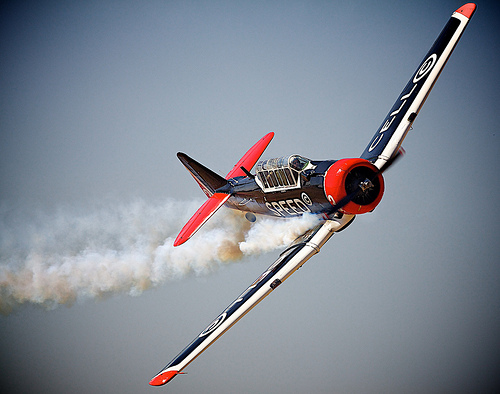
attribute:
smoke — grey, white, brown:
[2, 194, 312, 313]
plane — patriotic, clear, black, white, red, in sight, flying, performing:
[173, 1, 477, 347]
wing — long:
[147, 217, 338, 388]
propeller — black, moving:
[321, 141, 407, 224]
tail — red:
[174, 132, 276, 246]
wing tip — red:
[147, 370, 174, 385]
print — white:
[366, 51, 438, 154]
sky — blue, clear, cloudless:
[8, 4, 499, 347]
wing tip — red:
[451, 1, 479, 18]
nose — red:
[325, 157, 387, 216]